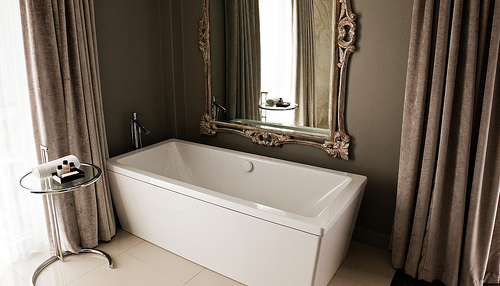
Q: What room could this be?
A: It is a bathroom.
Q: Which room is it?
A: It is a bathroom.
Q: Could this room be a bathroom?
A: Yes, it is a bathroom.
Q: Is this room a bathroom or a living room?
A: It is a bathroom.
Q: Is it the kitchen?
A: No, it is the bathroom.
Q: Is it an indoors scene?
A: Yes, it is indoors.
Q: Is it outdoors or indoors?
A: It is indoors.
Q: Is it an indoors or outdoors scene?
A: It is indoors.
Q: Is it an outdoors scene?
A: No, it is indoors.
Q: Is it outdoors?
A: No, it is indoors.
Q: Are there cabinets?
A: No, there are no cabinets.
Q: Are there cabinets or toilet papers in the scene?
A: No, there are no cabinets or toilet papers.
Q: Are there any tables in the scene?
A: Yes, there is a table.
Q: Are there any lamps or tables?
A: Yes, there is a table.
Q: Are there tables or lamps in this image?
A: Yes, there is a table.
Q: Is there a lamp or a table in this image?
A: Yes, there is a table.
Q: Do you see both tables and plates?
A: No, there is a table but no plates.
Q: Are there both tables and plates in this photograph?
A: No, there is a table but no plates.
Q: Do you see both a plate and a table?
A: No, there is a table but no plates.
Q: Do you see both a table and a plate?
A: No, there is a table but no plates.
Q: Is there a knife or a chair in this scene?
A: No, there are no chairs or knives.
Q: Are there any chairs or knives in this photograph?
A: No, there are no chairs or knives.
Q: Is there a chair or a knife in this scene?
A: No, there are no chairs or knives.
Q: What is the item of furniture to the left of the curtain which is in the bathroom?
A: The piece of furniture is a table.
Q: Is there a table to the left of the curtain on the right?
A: Yes, there is a table to the left of the curtain.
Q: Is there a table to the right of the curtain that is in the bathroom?
A: No, the table is to the left of the curtain.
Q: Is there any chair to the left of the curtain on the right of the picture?
A: No, there is a table to the left of the curtain.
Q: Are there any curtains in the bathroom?
A: Yes, there is a curtain in the bathroom.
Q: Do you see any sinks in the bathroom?
A: No, there is a curtain in the bathroom.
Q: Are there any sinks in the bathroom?
A: No, there is a curtain in the bathroom.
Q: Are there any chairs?
A: No, there are no chairs.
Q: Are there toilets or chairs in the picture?
A: No, there are no chairs or toilets.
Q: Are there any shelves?
A: No, there are no shelves.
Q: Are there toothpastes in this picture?
A: No, there are no toothpastes.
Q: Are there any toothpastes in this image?
A: No, there are no toothpastes.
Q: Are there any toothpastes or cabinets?
A: No, there are no toothpastes or cabinets.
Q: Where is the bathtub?
A: The bathtub is in the bathroom.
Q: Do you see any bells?
A: No, there are no bells.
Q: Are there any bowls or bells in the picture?
A: No, there are no bells or bowls.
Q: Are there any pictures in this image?
A: No, there are no pictures.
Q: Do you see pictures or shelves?
A: No, there are no pictures or shelves.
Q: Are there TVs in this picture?
A: No, there are no tvs.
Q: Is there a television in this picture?
A: No, there are no televisions.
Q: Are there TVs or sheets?
A: No, there are no TVs or sheets.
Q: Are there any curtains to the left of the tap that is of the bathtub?
A: Yes, there is a curtain to the left of the tap.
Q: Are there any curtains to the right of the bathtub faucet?
A: No, the curtain is to the left of the faucet.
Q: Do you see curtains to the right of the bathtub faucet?
A: No, the curtain is to the left of the faucet.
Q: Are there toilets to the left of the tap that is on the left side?
A: No, there is a curtain to the left of the faucet.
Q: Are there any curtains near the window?
A: Yes, there is a curtain near the window.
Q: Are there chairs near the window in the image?
A: No, there is a curtain near the window.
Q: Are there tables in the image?
A: Yes, there is a table.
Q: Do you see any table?
A: Yes, there is a table.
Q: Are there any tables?
A: Yes, there is a table.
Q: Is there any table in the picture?
A: Yes, there is a table.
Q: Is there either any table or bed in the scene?
A: Yes, there is a table.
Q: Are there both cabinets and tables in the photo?
A: No, there is a table but no cabinets.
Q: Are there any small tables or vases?
A: Yes, there is a small table.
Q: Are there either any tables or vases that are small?
A: Yes, the table is small.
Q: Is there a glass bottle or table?
A: Yes, there is a glass table.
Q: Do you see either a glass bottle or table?
A: Yes, there is a glass table.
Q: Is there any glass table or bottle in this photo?
A: Yes, there is a glass table.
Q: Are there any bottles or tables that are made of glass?
A: Yes, the table is made of glass.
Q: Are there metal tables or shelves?
A: Yes, there is a metal table.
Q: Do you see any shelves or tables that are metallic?
A: Yes, the table is metallic.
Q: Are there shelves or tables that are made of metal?
A: Yes, the table is made of metal.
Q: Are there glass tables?
A: Yes, there is a table that is made of glass.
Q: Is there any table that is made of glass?
A: Yes, there is a table that is made of glass.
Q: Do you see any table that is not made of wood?
A: Yes, there is a table that is made of glass.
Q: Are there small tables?
A: Yes, there is a small table.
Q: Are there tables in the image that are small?
A: Yes, there is a table that is small.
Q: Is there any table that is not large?
A: Yes, there is a small table.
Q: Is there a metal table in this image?
A: Yes, there is a metal table.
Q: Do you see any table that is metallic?
A: Yes, there is a table that is metallic.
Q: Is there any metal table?
A: Yes, there is a table that is made of metal.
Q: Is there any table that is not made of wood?
A: Yes, there is a table that is made of metal.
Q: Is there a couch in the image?
A: No, there are no couches.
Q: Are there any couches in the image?
A: No, there are no couches.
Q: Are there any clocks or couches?
A: No, there are no couches or clocks.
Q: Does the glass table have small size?
A: Yes, the table is small.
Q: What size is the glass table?
A: The table is small.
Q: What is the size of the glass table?
A: The table is small.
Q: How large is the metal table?
A: The table is small.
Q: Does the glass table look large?
A: No, the table is small.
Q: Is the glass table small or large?
A: The table is small.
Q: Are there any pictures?
A: No, there are no pictures.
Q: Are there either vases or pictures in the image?
A: No, there are no pictures or vases.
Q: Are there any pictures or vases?
A: No, there are no pictures or vases.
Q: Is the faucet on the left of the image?
A: Yes, the faucet is on the left of the image.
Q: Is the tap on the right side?
A: No, the tap is on the left of the image.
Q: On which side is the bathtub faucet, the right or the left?
A: The faucet is on the left of the image.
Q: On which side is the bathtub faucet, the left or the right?
A: The faucet is on the left of the image.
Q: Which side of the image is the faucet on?
A: The faucet is on the left of the image.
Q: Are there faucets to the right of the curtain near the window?
A: Yes, there is a faucet to the right of the curtain.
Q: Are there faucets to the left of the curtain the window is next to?
A: No, the faucet is to the right of the curtain.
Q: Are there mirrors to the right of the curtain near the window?
A: No, there is a faucet to the right of the curtain.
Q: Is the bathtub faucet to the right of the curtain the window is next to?
A: Yes, the tap is to the right of the curtain.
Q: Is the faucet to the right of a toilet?
A: No, the faucet is to the right of the curtain.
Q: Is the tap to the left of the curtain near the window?
A: No, the tap is to the right of the curtain.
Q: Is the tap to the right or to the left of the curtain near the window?
A: The tap is to the right of the curtain.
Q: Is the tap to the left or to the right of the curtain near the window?
A: The tap is to the right of the curtain.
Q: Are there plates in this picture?
A: No, there are no plates.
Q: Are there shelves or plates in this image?
A: No, there are no plates or shelves.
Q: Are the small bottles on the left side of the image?
A: Yes, the bottles are on the left of the image.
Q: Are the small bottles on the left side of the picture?
A: Yes, the bottles are on the left of the image.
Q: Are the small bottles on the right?
A: No, the bottles are on the left of the image.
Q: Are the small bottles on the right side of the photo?
A: No, the bottles are on the left of the image.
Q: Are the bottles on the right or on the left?
A: The bottles are on the left of the image.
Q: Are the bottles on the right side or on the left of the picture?
A: The bottles are on the left of the image.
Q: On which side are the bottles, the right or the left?
A: The bottles are on the left of the image.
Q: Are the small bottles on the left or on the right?
A: The bottles are on the left of the image.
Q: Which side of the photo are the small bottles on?
A: The bottles are on the left of the image.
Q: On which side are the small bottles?
A: The bottles are on the left of the image.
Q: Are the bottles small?
A: Yes, the bottles are small.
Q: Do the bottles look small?
A: Yes, the bottles are small.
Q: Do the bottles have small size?
A: Yes, the bottles are small.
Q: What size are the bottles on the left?
A: The bottles are small.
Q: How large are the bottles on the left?
A: The bottles are small.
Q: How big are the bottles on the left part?
A: The bottles are small.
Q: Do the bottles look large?
A: No, the bottles are small.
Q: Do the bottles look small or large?
A: The bottles are small.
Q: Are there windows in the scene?
A: Yes, there is a window.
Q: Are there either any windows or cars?
A: Yes, there is a window.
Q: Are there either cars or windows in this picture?
A: Yes, there is a window.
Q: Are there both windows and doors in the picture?
A: No, there is a window but no doors.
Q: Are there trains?
A: No, there are no trains.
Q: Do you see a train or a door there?
A: No, there are no trains or doors.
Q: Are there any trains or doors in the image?
A: No, there are no trains or doors.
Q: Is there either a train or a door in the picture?
A: No, there are no trains or doors.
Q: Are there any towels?
A: Yes, there is a towel.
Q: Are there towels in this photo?
A: Yes, there is a towel.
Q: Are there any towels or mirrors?
A: Yes, there is a towel.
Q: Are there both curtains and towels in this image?
A: Yes, there are both a towel and a curtain.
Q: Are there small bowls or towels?
A: Yes, there is a small towel.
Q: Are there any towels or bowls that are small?
A: Yes, the towel is small.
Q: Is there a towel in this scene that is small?
A: Yes, there is a small towel.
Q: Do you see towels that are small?
A: Yes, there is a towel that is small.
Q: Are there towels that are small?
A: Yes, there is a towel that is small.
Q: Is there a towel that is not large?
A: Yes, there is a small towel.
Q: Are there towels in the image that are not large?
A: Yes, there is a small towel.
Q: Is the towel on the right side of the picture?
A: No, the towel is on the left of the image.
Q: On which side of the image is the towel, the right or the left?
A: The towel is on the left of the image.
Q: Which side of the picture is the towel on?
A: The towel is on the left of the image.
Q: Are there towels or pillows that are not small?
A: No, there is a towel but it is small.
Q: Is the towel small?
A: Yes, the towel is small.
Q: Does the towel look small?
A: Yes, the towel is small.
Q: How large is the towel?
A: The towel is small.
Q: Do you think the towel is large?
A: No, the towel is small.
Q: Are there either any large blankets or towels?
A: No, there is a towel but it is small.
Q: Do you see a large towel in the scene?
A: No, there is a towel but it is small.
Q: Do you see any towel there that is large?
A: No, there is a towel but it is small.